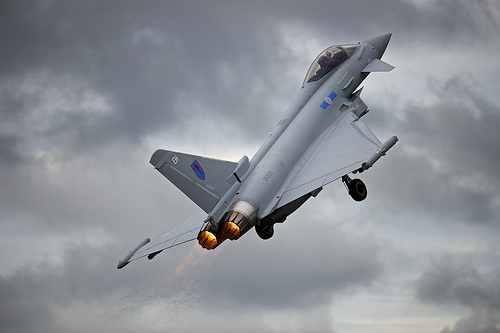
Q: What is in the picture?
A: An airplane.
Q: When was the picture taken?
A: During takeoff.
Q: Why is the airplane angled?
A: It is taking off.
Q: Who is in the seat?
A: The pilot.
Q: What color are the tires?
A: Black.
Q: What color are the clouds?
A: Gray.